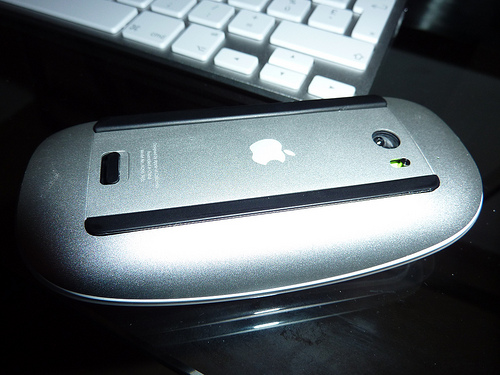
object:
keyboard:
[29, 0, 410, 122]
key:
[277, 22, 348, 74]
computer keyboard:
[0, 2, 410, 100]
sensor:
[370, 125, 400, 150]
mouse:
[19, 93, 486, 308]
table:
[0, 0, 499, 374]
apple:
[249, 138, 294, 164]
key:
[212, 50, 264, 77]